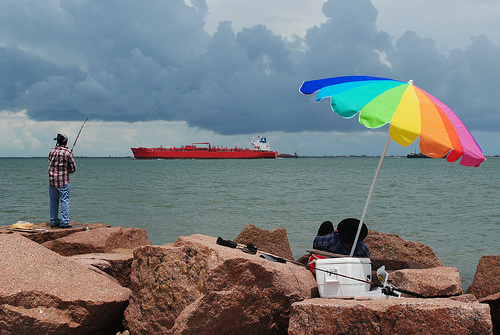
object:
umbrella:
[297, 75, 487, 257]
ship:
[130, 136, 278, 160]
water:
[0, 157, 499, 295]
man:
[47, 133, 78, 230]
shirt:
[47, 145, 77, 188]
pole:
[70, 119, 87, 153]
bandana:
[58, 133, 68, 144]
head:
[56, 133, 68, 146]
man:
[312, 217, 372, 258]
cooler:
[315, 257, 372, 300]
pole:
[237, 244, 430, 299]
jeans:
[49, 183, 70, 227]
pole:
[347, 137, 391, 258]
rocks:
[0, 226, 132, 334]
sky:
[0, 0, 499, 157]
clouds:
[21, 45, 189, 123]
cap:
[336, 217, 368, 242]